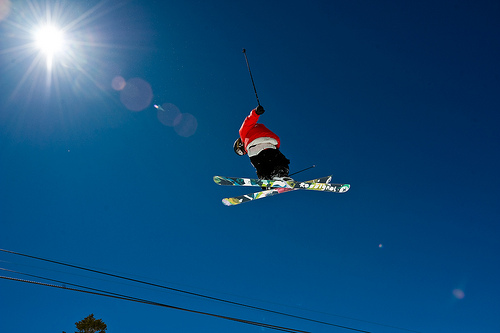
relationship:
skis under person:
[212, 174, 351, 207] [232, 107, 295, 191]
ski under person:
[212, 175, 352, 193] [232, 107, 295, 191]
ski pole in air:
[242, 48, 262, 107] [0, 0, 498, 332]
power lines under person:
[0, 249, 414, 332] [232, 107, 295, 191]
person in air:
[232, 107, 295, 191] [0, 0, 498, 332]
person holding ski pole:
[232, 107, 295, 191] [242, 48, 262, 107]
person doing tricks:
[232, 107, 295, 191] [213, 47, 350, 207]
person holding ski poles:
[232, 107, 295, 191] [241, 47, 316, 176]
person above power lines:
[232, 107, 295, 191] [0, 249, 414, 332]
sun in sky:
[1, 2, 146, 122] [0, 0, 498, 332]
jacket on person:
[238, 108, 281, 153] [232, 107, 295, 191]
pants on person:
[250, 148, 290, 192] [232, 107, 295, 191]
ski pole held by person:
[242, 48, 262, 107] [232, 107, 295, 191]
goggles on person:
[236, 147, 246, 158] [232, 107, 295, 191]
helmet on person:
[232, 136, 246, 157] [232, 107, 295, 191]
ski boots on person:
[263, 169, 295, 191] [232, 107, 295, 191]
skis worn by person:
[212, 174, 351, 207] [232, 107, 295, 191]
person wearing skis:
[232, 107, 295, 191] [212, 174, 351, 207]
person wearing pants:
[232, 107, 295, 191] [250, 148, 290, 192]